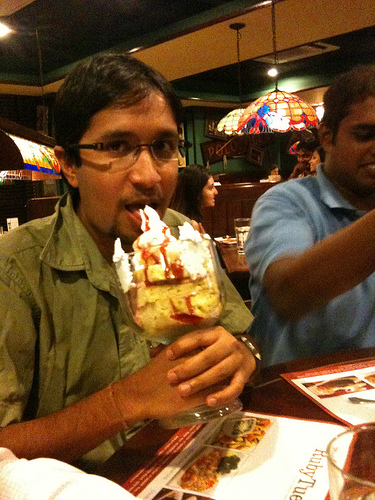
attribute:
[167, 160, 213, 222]
hair — black, long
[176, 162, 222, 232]
woman — black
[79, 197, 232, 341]
ice cream — delicious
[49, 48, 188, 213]
hair — brown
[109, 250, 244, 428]
glass — tall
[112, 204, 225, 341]
ice cream — delicious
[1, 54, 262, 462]
man — fat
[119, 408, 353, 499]
paper — showing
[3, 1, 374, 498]
restaurant — exciting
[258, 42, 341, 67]
vent — white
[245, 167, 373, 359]
shirt — blue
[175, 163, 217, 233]
woman — talking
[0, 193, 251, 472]
shirt — green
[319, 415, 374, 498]
cup — glass, transparent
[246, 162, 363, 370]
shirt — blue